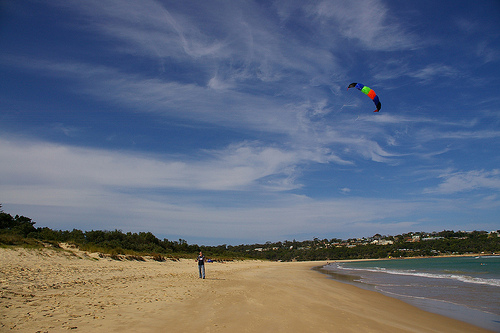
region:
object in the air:
[310, 60, 406, 145]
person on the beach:
[165, 240, 230, 295]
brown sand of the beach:
[225, 270, 311, 330]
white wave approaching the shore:
[410, 250, 465, 296]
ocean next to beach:
[421, 250, 481, 306]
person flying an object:
[155, 225, 225, 296]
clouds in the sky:
[163, 95, 320, 193]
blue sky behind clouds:
[60, 83, 147, 139]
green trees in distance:
[118, 219, 171, 259]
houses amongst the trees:
[326, 223, 399, 269]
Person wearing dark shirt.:
[189, 258, 203, 262]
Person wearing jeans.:
[195, 242, 222, 312]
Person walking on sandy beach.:
[191, 239, 226, 325]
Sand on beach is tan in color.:
[123, 262, 265, 324]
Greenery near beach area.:
[107, 225, 169, 284]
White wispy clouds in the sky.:
[150, 110, 288, 213]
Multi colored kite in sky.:
[344, 71, 409, 161]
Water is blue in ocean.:
[427, 265, 476, 327]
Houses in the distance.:
[324, 210, 459, 280]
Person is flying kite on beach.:
[143, 238, 291, 299]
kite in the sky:
[339, 74, 391, 125]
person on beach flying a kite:
[183, 244, 212, 286]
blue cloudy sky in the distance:
[24, 8, 317, 215]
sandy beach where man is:
[154, 287, 345, 331]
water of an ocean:
[381, 256, 493, 301]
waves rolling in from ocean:
[369, 266, 443, 281]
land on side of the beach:
[281, 226, 498, 258]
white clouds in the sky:
[210, 135, 274, 192]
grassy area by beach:
[5, 211, 167, 259]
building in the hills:
[405, 233, 427, 244]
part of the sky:
[350, 150, 407, 213]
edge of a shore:
[340, 266, 395, 312]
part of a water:
[400, 253, 454, 284]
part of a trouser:
[196, 267, 206, 274]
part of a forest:
[116, 232, 161, 259]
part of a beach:
[227, 279, 257, 305]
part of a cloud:
[194, 137, 242, 189]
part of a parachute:
[369, 88, 385, 110]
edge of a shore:
[358, 270, 410, 321]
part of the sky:
[157, 120, 199, 146]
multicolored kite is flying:
[337, 67, 391, 139]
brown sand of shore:
[250, 257, 322, 317]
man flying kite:
[171, 245, 231, 303]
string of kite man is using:
[249, 138, 329, 223]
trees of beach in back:
[6, 223, 110, 274]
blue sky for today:
[120, 78, 280, 153]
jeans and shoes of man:
[190, 269, 208, 277]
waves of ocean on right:
[372, 254, 486, 324]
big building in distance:
[349, 232, 396, 262]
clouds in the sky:
[187, 129, 282, 204]